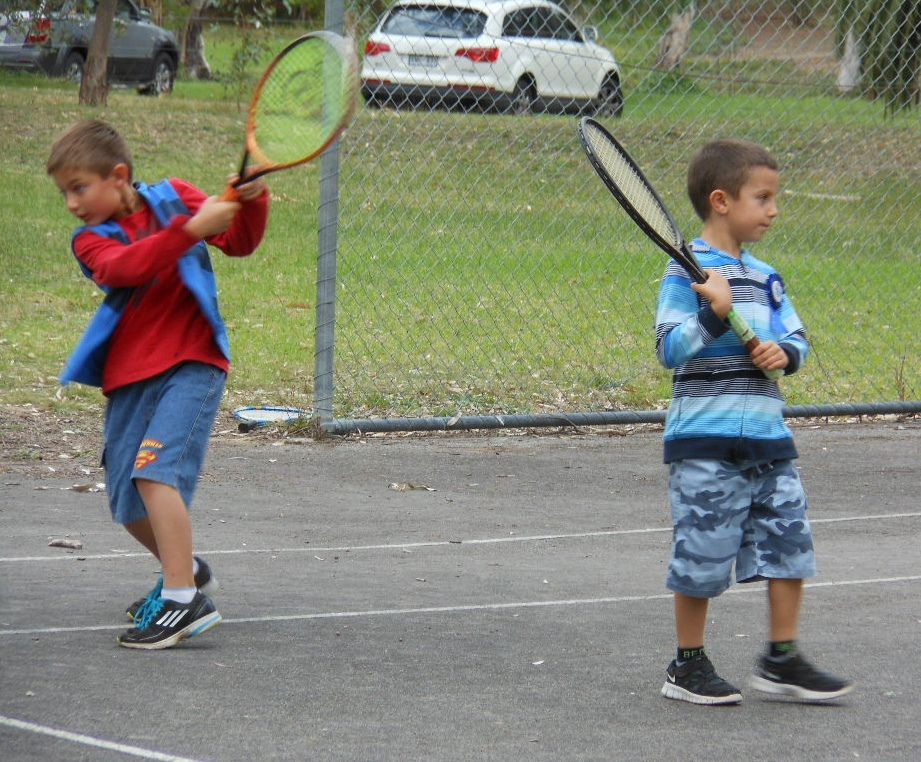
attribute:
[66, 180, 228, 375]
vest — blue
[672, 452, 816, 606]
shorts — blue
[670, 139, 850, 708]
boy — holding , wearing  ,  wearing 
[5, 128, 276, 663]
boy — holding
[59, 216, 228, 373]
shirt —  red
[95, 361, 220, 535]
shorts — blue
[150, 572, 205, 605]
socks — white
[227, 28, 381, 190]
tennis racket — orange, black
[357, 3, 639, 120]
suv — small, white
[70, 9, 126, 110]
tree trunk — brown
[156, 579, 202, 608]
sock — blue, white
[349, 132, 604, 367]
grass — green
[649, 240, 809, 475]
shirt — blue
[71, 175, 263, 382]
shirt — red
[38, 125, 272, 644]
boy — young, wearing, black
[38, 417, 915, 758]
court — tennis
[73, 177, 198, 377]
shirts — blue